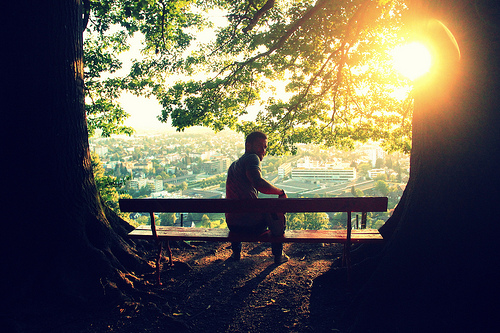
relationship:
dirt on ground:
[162, 252, 308, 327] [162, 278, 290, 325]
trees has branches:
[339, 0, 497, 333] [215, 7, 400, 126]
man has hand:
[222, 129, 295, 262] [253, 174, 288, 200]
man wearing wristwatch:
[222, 129, 295, 262] [276, 188, 285, 199]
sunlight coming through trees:
[371, 19, 463, 109] [0, 3, 497, 328]